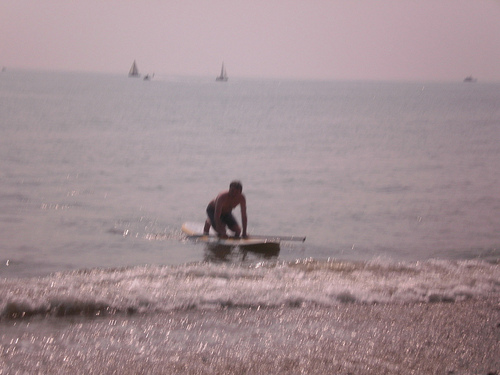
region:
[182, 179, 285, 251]
Man kneeling on surfboard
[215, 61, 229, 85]
Sailboat on the ocean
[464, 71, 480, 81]
Ship out on the ocean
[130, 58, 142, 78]
Sailing boat in the ocean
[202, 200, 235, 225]
Black shorts on man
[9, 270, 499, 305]
White froth from waves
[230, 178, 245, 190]
Dark hair on man's head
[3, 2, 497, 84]
White skyline behind boats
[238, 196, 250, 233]
Man's arm on surfboard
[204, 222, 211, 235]
Man's foot on surfboard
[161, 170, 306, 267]
surfer in the ocean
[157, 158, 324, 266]
surfer in the ocean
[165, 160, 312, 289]
A man kneeling on a surfboard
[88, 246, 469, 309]
A small wave in the ocean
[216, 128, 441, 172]
Calm blue ocean water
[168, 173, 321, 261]
A man floating on a surfboard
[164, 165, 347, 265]
A man riding a surfboard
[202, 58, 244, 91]
A sailboat in the ocean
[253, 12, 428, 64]
A gray cloudy sky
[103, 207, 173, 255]
Ocean water sparkling in the sun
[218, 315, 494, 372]
A wet sandy shore surface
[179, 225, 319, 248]
An oar on a surfboard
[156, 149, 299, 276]
a man on a surfboard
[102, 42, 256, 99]
sailboats in the distance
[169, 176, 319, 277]
man on a surfboard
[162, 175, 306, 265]
man kneeling on the surfboard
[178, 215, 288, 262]
surfboard floating on top of the water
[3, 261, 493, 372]
small wave in the water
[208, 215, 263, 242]
both hands on the board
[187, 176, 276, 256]
man is not wearing a shirt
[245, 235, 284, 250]
front of the board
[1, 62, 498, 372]
calm body of water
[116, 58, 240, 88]
small boats on the water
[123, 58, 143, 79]
sails on the boat